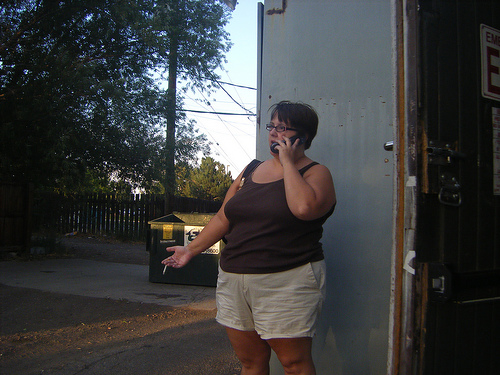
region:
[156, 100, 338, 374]
Woman talking on the phone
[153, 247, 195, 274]
Cigarette in woman's hand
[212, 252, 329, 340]
White shorts on woman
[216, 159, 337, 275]
Brown tank top on woman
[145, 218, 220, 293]
Dumpster on the pavement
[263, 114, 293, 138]
Glasses over woman's eyes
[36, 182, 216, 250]
Brown fence in the background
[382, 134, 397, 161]
Silver lock on the door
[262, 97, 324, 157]
Woman holding phone to her ear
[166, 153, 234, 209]
Trees in the distance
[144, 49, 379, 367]
this woman is talking on the phone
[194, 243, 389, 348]
a white pair of shorts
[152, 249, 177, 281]
this is a cigarette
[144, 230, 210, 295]
there is a cigarette in between her fingers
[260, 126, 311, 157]
a black cell phone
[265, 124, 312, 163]
this is a flip phone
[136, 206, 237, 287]
this is a green dumpster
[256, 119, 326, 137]
she is wearing glasses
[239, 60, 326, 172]
she has short hair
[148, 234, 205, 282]
hand holding a cigarette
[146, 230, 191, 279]
hand holding a cigarette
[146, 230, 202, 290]
hand holding a cigarette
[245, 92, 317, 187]
a woman talking on the phone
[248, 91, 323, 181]
a woman talking on the phone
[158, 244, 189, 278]
the woman is holding a cigarette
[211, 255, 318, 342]
tan shorts that the woman is wearing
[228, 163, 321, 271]
the woman is wearing a brown tank top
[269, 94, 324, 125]
the woman has short, brown hair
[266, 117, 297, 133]
the woman is wearing glasses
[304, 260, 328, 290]
the shorts have a pocket in them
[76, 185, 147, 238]
a wooden fence in the background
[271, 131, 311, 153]
the woman is talking on her phone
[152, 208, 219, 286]
a green dumpster behind the woman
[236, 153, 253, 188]
the womans purse strap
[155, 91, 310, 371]
a lady holding a cigarette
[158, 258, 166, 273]
the cigarette she is holding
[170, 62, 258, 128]
wires coming from the pole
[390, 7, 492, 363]
a wooden door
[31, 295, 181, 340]
leaves on the ground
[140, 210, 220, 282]
a green dumpster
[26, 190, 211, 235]
a wooden fence behind the dumpster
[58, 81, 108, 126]
green leave on the tree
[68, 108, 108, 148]
green leave on the tree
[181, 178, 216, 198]
green leave on the tree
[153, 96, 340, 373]
woman standing outside and talking on cellular phone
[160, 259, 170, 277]
white cigarrette in woman's hand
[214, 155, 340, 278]
brown tank top on woman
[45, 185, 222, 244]
wooden fence behind building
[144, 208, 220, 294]
green metal dumpster on side of building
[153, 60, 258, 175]
black power lines in sky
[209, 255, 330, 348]
tan shorts on woman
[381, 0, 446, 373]
open wooden door on side of building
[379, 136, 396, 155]
silver lever door handle